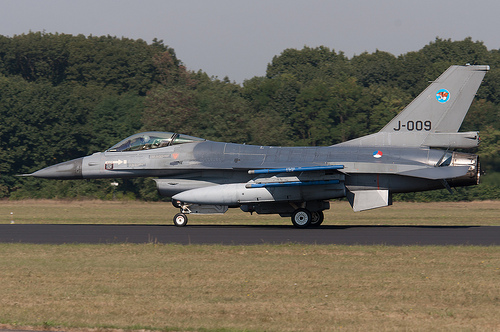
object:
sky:
[0, 0, 499, 87]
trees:
[0, 76, 135, 199]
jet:
[20, 63, 488, 229]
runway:
[0, 221, 499, 246]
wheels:
[302, 208, 322, 228]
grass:
[0, 242, 498, 332]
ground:
[0, 196, 498, 332]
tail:
[378, 63, 491, 145]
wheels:
[288, 210, 313, 227]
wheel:
[170, 213, 190, 228]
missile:
[166, 175, 342, 207]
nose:
[16, 164, 56, 180]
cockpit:
[111, 131, 184, 154]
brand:
[372, 150, 382, 157]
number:
[403, 120, 428, 131]